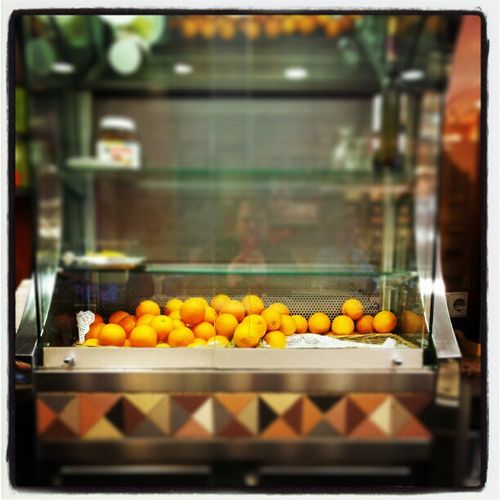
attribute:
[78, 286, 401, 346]
oranges — stacked, reflecting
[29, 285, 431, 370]
rack — glass, metal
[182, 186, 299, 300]
reflection — guy, man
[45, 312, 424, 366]
tray — white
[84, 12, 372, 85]
reflection — oranges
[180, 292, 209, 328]
orange — here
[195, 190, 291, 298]
photographer — reflected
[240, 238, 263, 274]
mobile phone — red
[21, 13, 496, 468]
picture — vertical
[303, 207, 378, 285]
person — captured, looking away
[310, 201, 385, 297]
individual — woman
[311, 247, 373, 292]
shirt — button down, blue, white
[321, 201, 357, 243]
hair — blond, curly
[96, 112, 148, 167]
jar — blurry, standing alone, nutella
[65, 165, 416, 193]
shelf — glass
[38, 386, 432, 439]
strip — mosaic, tile, triangles, warm colors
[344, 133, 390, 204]
bottle — reflected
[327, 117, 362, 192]
bottle — reflected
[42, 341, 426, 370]
piece — metal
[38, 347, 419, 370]
item — silver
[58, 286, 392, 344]
enclosure — metal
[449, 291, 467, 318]
knob — white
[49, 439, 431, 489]
door — glass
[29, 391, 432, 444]
shapes — triangular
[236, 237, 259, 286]
cup — red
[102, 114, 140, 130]
lid — white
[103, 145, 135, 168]
lettering — red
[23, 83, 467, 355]
light — reflecting